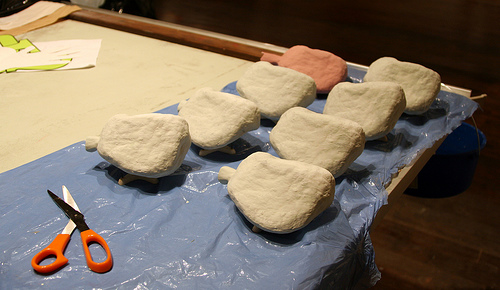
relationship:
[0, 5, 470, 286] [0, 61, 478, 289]
table top covered with plastic bag